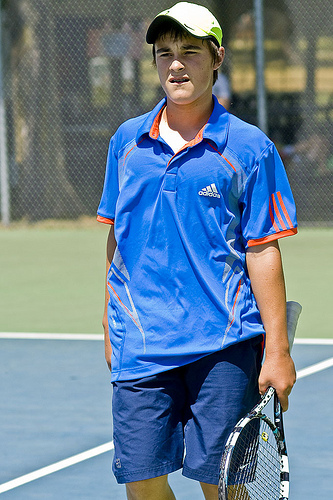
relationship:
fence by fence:
[0, 0, 333, 229] [1, 1, 330, 224]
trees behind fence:
[279, 3, 332, 108] [0, 0, 333, 229]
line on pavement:
[299, 358, 320, 382] [9, 330, 328, 487]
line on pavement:
[16, 435, 106, 494] [4, 217, 322, 483]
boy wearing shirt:
[96, 0, 298, 497] [95, 97, 298, 382]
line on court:
[0, 440, 114, 495] [0, 0, 333, 500]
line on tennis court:
[29, 324, 69, 345] [1, 312, 106, 417]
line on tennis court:
[299, 358, 320, 382] [1, 312, 106, 417]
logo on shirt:
[196, 181, 218, 196] [95, 97, 298, 382]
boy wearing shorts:
[97, 2, 296, 497] [104, 319, 262, 487]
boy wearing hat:
[97, 2, 296, 497] [145, 1, 222, 47]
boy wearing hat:
[97, 2, 296, 497] [146, 0, 224, 53]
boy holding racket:
[96, 0, 298, 497] [205, 286, 309, 497]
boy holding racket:
[97, 2, 296, 497] [217, 301, 303, 499]